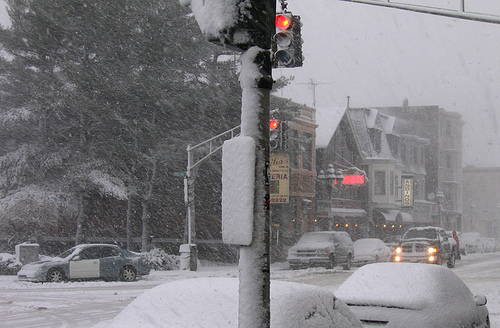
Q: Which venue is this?
A: This is a road.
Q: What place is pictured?
A: It is a road.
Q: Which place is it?
A: It is a road.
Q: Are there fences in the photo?
A: No, there are no fences.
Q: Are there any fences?
A: No, there are no fences.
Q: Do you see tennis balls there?
A: No, there are no tennis balls.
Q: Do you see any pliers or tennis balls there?
A: No, there are no tennis balls or pliers.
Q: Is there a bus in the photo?
A: No, there are no buses.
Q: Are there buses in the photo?
A: No, there are no buses.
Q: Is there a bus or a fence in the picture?
A: No, there are no buses or fences.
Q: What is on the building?
A: The sign is on the building.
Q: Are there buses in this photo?
A: No, there are no buses.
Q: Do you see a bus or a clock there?
A: No, there are no buses or clocks.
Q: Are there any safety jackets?
A: No, there are no safety jackets.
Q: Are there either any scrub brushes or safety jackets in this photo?
A: No, there are no safety jackets or scrub brushes.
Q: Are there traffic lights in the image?
A: Yes, there is a traffic light.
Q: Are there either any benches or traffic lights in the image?
A: Yes, there is a traffic light.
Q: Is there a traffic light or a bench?
A: Yes, there is a traffic light.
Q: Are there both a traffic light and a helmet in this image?
A: No, there is a traffic light but no helmets.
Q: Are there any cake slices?
A: No, there are no cake slices.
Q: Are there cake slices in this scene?
A: No, there are no cake slices.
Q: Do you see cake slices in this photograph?
A: No, there are no cake slices.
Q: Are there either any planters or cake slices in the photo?
A: No, there are no cake slices or planters.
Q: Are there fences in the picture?
A: No, there are no fences.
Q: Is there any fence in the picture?
A: No, there are no fences.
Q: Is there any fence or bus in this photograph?
A: No, there are no fences or buses.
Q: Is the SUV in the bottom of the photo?
A: Yes, the SUV is in the bottom of the image.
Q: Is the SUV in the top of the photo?
A: No, the SUV is in the bottom of the image.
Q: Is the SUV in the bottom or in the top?
A: The SUV is in the bottom of the image.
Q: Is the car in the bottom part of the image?
A: Yes, the car is in the bottom of the image.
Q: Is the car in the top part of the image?
A: No, the car is in the bottom of the image.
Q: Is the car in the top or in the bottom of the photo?
A: The car is in the bottom of the image.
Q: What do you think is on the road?
A: The car is on the road.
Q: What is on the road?
A: The car is on the road.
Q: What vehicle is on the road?
A: The vehicle is a car.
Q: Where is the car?
A: The car is on the road.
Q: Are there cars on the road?
A: Yes, there is a car on the road.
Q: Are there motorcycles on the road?
A: No, there is a car on the road.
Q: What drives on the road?
A: The car drives on the road.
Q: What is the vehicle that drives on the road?
A: The vehicle is a car.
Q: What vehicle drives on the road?
A: The vehicle is a car.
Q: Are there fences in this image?
A: No, there are no fences.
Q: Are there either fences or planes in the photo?
A: No, there are no fences or planes.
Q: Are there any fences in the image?
A: No, there are no fences.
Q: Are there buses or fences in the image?
A: No, there are no fences or buses.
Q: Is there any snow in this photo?
A: Yes, there is snow.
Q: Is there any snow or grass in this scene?
A: Yes, there is snow.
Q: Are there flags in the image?
A: No, there are no flags.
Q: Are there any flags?
A: No, there are no flags.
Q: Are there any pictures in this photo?
A: No, there are no pictures.